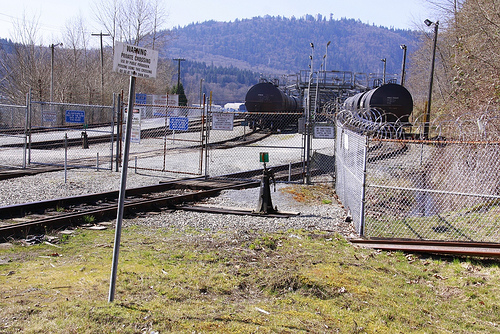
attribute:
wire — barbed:
[317, 96, 500, 146]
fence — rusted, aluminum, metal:
[326, 117, 500, 241]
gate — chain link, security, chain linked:
[28, 88, 206, 186]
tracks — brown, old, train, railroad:
[2, 114, 281, 178]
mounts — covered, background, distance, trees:
[111, 8, 441, 93]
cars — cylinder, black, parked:
[359, 84, 417, 138]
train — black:
[337, 79, 413, 131]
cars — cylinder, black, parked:
[244, 77, 298, 135]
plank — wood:
[351, 232, 499, 265]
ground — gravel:
[1, 120, 432, 234]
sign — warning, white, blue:
[108, 36, 159, 82]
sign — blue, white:
[67, 107, 85, 123]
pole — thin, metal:
[106, 73, 137, 302]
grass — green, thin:
[8, 219, 495, 333]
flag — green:
[258, 150, 272, 164]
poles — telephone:
[92, 28, 118, 117]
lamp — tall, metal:
[416, 15, 442, 143]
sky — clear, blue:
[1, 1, 500, 58]